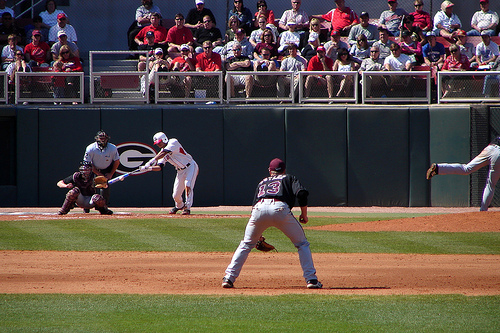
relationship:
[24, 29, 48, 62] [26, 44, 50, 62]
man has shirt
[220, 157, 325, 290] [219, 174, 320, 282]
pitcher has uniform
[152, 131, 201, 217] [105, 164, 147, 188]
player has bat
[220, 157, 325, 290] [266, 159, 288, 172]
pitcher has cap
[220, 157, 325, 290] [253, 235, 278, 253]
pitcher has glove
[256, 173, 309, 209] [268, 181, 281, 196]
shirt has number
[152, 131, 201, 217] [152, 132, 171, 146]
player has helmet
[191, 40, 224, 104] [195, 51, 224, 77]
person wears red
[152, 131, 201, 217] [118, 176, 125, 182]
player hits ball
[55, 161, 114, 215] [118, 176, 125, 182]
catcher catches ball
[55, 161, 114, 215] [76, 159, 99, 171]
catcher has helmet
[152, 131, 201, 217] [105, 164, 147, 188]
player swings bat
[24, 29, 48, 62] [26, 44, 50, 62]
man wears shirt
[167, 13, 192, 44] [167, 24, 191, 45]
man wears shirt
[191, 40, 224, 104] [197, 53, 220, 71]
person wears shirt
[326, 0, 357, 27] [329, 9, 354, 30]
man wears shirt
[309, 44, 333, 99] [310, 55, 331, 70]
man wears shirt